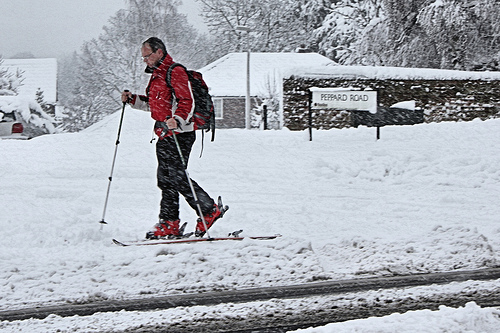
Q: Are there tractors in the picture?
A: No, there are no tractors.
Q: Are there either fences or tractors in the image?
A: No, there are no tractors or fences.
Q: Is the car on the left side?
A: Yes, the car is on the left of the image.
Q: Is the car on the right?
A: No, the car is on the left of the image.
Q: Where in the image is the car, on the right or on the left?
A: The car is on the left of the image.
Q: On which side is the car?
A: The car is on the left of the image.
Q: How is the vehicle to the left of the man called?
A: The vehicle is a car.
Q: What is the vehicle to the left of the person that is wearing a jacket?
A: The vehicle is a car.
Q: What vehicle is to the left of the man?
A: The vehicle is a car.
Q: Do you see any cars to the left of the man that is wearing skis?
A: Yes, there is a car to the left of the man.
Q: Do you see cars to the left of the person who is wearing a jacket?
A: Yes, there is a car to the left of the man.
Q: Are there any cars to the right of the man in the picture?
A: No, the car is to the left of the man.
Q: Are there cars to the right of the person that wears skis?
A: No, the car is to the left of the man.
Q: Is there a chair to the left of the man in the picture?
A: No, there is a car to the left of the man.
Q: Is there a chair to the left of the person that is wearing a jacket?
A: No, there is a car to the left of the man.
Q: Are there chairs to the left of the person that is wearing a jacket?
A: No, there is a car to the left of the man.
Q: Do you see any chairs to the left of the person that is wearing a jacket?
A: No, there is a car to the left of the man.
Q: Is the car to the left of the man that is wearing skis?
A: Yes, the car is to the left of the man.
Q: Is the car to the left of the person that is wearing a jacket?
A: Yes, the car is to the left of the man.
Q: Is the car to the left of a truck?
A: No, the car is to the left of the man.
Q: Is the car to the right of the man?
A: No, the car is to the left of the man.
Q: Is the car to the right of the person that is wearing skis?
A: No, the car is to the left of the man.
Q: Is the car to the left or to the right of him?
A: The car is to the left of the man.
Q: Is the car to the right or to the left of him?
A: The car is to the left of the man.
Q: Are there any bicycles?
A: No, there are no bicycles.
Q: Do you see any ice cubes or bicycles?
A: No, there are no bicycles or ice cubes.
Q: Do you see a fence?
A: No, there are no fences.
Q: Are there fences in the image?
A: No, there are no fences.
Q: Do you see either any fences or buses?
A: No, there are no fences or buses.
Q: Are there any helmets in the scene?
A: No, there are no helmets.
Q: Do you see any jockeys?
A: No, there are no jockeys.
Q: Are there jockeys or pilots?
A: No, there are no jockeys or pilots.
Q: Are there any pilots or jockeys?
A: No, there are no jockeys or pilots.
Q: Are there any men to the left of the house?
A: Yes, there is a man to the left of the house.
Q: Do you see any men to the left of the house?
A: Yes, there is a man to the left of the house.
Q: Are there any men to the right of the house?
A: No, the man is to the left of the house.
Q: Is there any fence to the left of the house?
A: No, there is a man to the left of the house.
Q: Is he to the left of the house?
A: Yes, the man is to the left of the house.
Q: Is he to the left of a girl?
A: No, the man is to the left of the house.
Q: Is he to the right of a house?
A: No, the man is to the left of a house.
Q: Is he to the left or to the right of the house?
A: The man is to the left of the house.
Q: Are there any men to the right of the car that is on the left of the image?
A: Yes, there is a man to the right of the car.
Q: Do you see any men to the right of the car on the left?
A: Yes, there is a man to the right of the car.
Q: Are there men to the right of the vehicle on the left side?
A: Yes, there is a man to the right of the car.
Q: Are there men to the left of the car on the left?
A: No, the man is to the right of the car.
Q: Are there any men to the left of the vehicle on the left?
A: No, the man is to the right of the car.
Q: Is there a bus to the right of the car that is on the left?
A: No, there is a man to the right of the car.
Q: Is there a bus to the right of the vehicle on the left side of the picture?
A: No, there is a man to the right of the car.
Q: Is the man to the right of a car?
A: Yes, the man is to the right of a car.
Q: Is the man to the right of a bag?
A: No, the man is to the right of a car.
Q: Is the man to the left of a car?
A: No, the man is to the right of a car.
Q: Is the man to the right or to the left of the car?
A: The man is to the right of the car.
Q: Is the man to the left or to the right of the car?
A: The man is to the right of the car.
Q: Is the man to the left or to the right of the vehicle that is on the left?
A: The man is to the right of the car.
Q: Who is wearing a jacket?
A: The man is wearing a jacket.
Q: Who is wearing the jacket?
A: The man is wearing a jacket.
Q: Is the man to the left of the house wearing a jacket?
A: Yes, the man is wearing a jacket.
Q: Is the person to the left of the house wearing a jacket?
A: Yes, the man is wearing a jacket.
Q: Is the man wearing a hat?
A: No, the man is wearing a jacket.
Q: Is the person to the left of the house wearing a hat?
A: No, the man is wearing a jacket.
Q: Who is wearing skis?
A: The man is wearing skis.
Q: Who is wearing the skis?
A: The man is wearing skis.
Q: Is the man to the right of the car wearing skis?
A: Yes, the man is wearing skis.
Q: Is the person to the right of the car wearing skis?
A: Yes, the man is wearing skis.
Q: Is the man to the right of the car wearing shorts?
A: No, the man is wearing skis.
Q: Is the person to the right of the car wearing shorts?
A: No, the man is wearing skis.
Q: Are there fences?
A: No, there are no fences.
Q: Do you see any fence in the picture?
A: No, there are no fences.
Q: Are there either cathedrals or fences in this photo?
A: No, there are no fences or cathedrals.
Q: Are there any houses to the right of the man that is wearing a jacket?
A: Yes, there is a house to the right of the man.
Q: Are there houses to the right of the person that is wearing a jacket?
A: Yes, there is a house to the right of the man.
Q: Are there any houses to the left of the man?
A: No, the house is to the right of the man.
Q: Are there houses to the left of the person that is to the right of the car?
A: No, the house is to the right of the man.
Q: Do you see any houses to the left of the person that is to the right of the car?
A: No, the house is to the right of the man.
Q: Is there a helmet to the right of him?
A: No, there is a house to the right of the man.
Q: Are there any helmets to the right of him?
A: No, there is a house to the right of the man.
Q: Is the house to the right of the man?
A: Yes, the house is to the right of the man.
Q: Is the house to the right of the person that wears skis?
A: Yes, the house is to the right of the man.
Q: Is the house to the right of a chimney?
A: No, the house is to the right of the man.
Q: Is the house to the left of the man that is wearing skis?
A: No, the house is to the right of the man.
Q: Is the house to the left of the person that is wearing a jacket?
A: No, the house is to the right of the man.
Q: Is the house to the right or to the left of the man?
A: The house is to the right of the man.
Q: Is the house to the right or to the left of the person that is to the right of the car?
A: The house is to the right of the man.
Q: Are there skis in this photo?
A: Yes, there are skis.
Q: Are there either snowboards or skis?
A: Yes, there are skis.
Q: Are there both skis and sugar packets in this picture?
A: No, there are skis but no sugar packets.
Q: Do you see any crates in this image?
A: No, there are no crates.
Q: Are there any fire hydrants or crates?
A: No, there are no crates or fire hydrants.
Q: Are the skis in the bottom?
A: Yes, the skis are in the bottom of the image.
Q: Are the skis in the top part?
A: No, the skis are in the bottom of the image.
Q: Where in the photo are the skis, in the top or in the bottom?
A: The skis are in the bottom of the image.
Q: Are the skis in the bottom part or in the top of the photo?
A: The skis are in the bottom of the image.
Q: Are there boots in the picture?
A: Yes, there are boots.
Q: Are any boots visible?
A: Yes, there are boots.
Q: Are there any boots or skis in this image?
A: Yes, there are boots.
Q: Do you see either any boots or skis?
A: Yes, there are boots.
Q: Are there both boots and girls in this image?
A: No, there are boots but no girls.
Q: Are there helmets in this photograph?
A: No, there are no helmets.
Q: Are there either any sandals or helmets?
A: No, there are no helmets or sandals.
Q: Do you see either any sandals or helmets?
A: No, there are no helmets or sandals.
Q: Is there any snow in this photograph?
A: Yes, there is snow.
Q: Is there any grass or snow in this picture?
A: Yes, there is snow.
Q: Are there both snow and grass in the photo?
A: No, there is snow but no grass.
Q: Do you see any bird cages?
A: No, there are no bird cages.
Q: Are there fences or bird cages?
A: No, there are no bird cages or fences.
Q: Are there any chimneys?
A: No, there are no chimneys.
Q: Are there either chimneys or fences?
A: No, there are no chimneys or fences.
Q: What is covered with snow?
A: The roof is covered with snow.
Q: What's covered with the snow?
A: The roof is covered with snow.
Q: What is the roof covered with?
A: The roof is covered with snow.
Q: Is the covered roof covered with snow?
A: Yes, the roof is covered with snow.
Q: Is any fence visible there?
A: No, there are no fences.